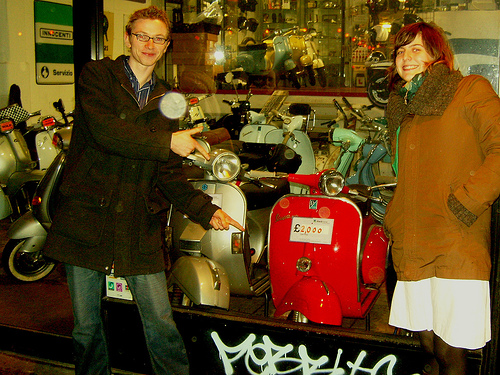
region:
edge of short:
[389, 303, 435, 335]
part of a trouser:
[143, 305, 173, 347]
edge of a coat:
[383, 267, 431, 293]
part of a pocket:
[147, 204, 177, 236]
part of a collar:
[138, 78, 150, 94]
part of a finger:
[227, 218, 243, 246]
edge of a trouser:
[134, 322, 151, 347]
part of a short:
[418, 282, 454, 309]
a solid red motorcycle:
[264, 158, 389, 333]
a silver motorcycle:
[160, 169, 273, 306]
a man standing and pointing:
[39, 4, 244, 372]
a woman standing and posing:
[376, 19, 497, 369]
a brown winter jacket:
[385, 67, 497, 277]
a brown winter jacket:
[44, 49, 224, 281]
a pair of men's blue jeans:
[58, 261, 188, 371]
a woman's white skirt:
[380, 264, 494, 351]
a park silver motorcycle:
[4, 131, 71, 283]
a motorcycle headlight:
[208, 149, 238, 184]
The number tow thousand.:
[286, 210, 346, 262]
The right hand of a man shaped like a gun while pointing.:
[162, 104, 227, 179]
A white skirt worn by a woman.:
[375, 252, 492, 352]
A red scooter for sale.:
[260, 153, 395, 351]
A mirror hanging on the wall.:
[160, 0, 417, 94]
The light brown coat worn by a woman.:
[384, 20, 481, 289]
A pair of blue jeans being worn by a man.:
[60, 215, 190, 374]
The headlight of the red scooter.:
[316, 160, 357, 210]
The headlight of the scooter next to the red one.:
[197, 136, 249, 198]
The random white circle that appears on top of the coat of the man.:
[153, 69, 188, 129]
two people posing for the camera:
[10, 4, 488, 372]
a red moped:
[250, 154, 400, 339]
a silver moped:
[162, 134, 267, 318]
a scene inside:
[17, 15, 487, 349]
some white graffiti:
[186, 312, 417, 372]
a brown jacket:
[359, 71, 499, 295]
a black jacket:
[37, 58, 219, 295]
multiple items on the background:
[17, 2, 484, 289]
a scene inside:
[12, 5, 482, 366]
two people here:
[0, 8, 477, 373]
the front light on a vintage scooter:
[202, 148, 239, 182]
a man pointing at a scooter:
[45, 7, 188, 366]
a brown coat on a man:
[38, 53, 220, 275]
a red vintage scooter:
[263, 153, 397, 329]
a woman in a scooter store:
[383, 24, 499, 373]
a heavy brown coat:
[374, 66, 494, 288]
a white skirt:
[390, 265, 496, 347]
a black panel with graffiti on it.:
[99, 293, 419, 373]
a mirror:
[149, 0, 403, 98]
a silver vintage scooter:
[152, 160, 269, 314]